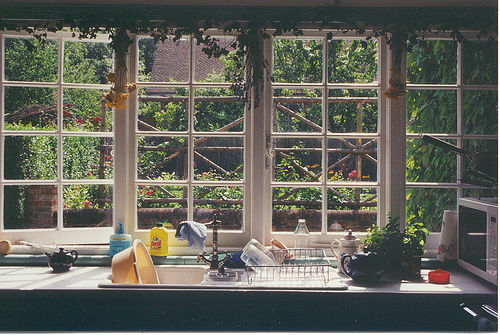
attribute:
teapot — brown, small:
[42, 244, 80, 274]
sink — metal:
[91, 241, 343, 293]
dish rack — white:
[212, 200, 349, 325]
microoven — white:
[445, 182, 497, 305]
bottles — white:
[234, 235, 349, 282]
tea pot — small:
[43, 245, 79, 274]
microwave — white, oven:
[452, 186, 498, 282]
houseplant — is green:
[351, 217, 411, 285]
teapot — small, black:
[41, 246, 77, 272]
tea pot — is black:
[337, 246, 391, 286]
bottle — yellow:
[145, 218, 172, 260]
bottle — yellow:
[149, 220, 171, 257]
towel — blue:
[176, 215, 211, 255]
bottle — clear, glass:
[258, 182, 318, 284]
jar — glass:
[287, 220, 315, 251]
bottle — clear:
[292, 215, 310, 262]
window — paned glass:
[276, 35, 371, 232]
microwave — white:
[454, 196, 498, 285]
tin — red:
[425, 267, 452, 289]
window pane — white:
[64, 87, 122, 132]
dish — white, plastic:
[241, 241, 341, 288]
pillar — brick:
[23, 185, 58, 228]